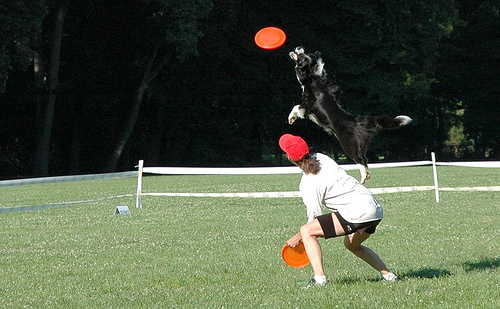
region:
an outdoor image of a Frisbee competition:
[1, 1, 499, 306]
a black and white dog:
[288, 44, 410, 184]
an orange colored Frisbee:
[253, 25, 285, 50]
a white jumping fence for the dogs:
[378, 152, 499, 197]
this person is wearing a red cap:
[276, 131, 310, 163]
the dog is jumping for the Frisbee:
[253, 24, 412, 185]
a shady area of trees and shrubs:
[1, 0, 253, 160]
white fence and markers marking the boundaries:
[1, 156, 284, 214]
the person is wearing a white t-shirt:
[299, 152, 384, 222]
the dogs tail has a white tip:
[365, 112, 412, 130]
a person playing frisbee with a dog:
[235, 18, 409, 293]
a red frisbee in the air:
[256, 21, 288, 49]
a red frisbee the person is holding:
[281, 241, 320, 268]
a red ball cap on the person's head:
[279, 132, 309, 162]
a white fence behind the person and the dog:
[135, 156, 497, 205]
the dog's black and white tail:
[381, 104, 417, 136]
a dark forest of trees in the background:
[8, 8, 250, 163]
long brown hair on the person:
[304, 158, 321, 173]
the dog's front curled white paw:
[286, 99, 309, 126]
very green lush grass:
[45, 221, 242, 299]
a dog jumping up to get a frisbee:
[281, 47, 415, 194]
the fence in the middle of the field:
[3, 158, 498, 215]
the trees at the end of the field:
[10, 6, 498, 164]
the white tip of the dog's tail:
[397, 112, 412, 125]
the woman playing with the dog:
[268, 131, 398, 286]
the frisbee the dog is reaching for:
[253, 22, 287, 53]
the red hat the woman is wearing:
[276, 133, 310, 162]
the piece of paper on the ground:
[113, 203, 133, 214]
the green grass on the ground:
[0, 161, 499, 306]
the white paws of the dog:
[282, 100, 307, 127]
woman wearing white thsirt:
[276, 131, 403, 287]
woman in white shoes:
[240, 132, 412, 292]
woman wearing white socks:
[267, 121, 420, 298]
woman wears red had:
[253, 129, 418, 291]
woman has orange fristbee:
[248, 128, 427, 294]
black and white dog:
[285, 44, 420, 167]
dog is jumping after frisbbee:
[226, 24, 410, 182]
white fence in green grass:
[12, 147, 497, 207]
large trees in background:
[38, 13, 497, 171]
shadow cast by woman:
[385, 253, 498, 280]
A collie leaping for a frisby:
[254, 20, 415, 187]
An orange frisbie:
[251, 15, 326, 79]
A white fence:
[3, 155, 498, 222]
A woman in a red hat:
[267, 130, 428, 301]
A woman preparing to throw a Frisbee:
[267, 127, 416, 307]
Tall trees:
[14, 3, 493, 183]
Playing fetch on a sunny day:
[216, 15, 446, 294]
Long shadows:
[272, 207, 499, 305]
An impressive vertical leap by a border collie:
[250, 23, 462, 289]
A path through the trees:
[417, 80, 497, 165]